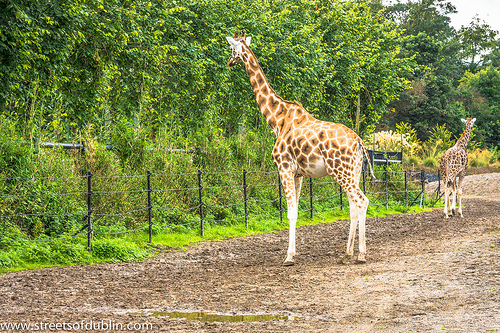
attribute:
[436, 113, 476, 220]
giraffe — moving away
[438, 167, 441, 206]
post — black, wooden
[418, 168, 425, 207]
post — black, wooden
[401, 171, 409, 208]
post — black, wooden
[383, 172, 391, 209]
post — black, wooden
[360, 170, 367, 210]
post — black, wooden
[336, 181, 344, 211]
post — black, wooden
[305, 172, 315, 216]
post — black, wooden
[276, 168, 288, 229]
post — black, wooden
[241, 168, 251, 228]
post — black, wooden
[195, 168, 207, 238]
post — black, wooden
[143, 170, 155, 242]
post — black, wooden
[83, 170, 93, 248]
post — black, wooden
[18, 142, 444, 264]
fence — long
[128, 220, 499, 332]
road — dirt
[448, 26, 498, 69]
sky patch — small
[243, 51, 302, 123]
neck — Extended , Long 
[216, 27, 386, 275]
giraffe — tall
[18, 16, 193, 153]
foliage — thick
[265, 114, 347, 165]
spots — unique  , brown 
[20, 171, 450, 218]
fence — Electric , Low Rised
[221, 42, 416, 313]
giraffe — tall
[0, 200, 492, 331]
dirt trail — Dirt , Long 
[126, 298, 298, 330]
puddle — Large 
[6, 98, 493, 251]
bushes — thick, green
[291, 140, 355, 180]
spots — brown, white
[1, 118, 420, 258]
vegetation — Mass amount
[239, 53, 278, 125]
neck — long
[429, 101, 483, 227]
giraffe — tall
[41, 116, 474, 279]
fence — wooden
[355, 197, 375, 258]
leg — white 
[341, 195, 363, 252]
leg — white 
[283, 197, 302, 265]
leg — white 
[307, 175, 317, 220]
fence post — black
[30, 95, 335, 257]
fence — black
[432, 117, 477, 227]
giraffe — Baby 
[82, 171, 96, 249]
post — black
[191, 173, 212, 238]
post — wooden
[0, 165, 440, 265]
fence — wire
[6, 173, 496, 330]
trail — dirt